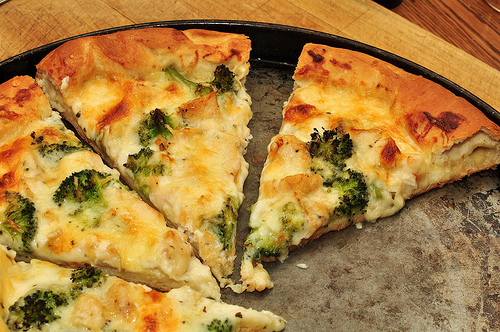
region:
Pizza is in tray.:
[46, 18, 470, 326]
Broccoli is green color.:
[47, 163, 109, 213]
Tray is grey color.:
[328, 198, 492, 328]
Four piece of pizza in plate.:
[38, 95, 300, 326]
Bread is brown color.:
[354, 61, 436, 117]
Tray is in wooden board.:
[262, 8, 456, 85]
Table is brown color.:
[417, 4, 492, 42]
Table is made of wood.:
[418, 5, 460, 50]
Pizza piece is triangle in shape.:
[208, 30, 488, 283]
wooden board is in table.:
[397, 11, 469, 55]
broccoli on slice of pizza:
[302, 122, 372, 217]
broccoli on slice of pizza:
[162, 62, 240, 104]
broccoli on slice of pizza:
[134, 107, 180, 147]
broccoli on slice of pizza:
[214, 194, 237, 250]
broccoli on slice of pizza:
[53, 172, 118, 215]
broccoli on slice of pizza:
[3, 190, 38, 249]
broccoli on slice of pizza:
[6, 287, 64, 327]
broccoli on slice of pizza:
[71, 263, 107, 294]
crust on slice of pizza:
[294, 43, 496, 172]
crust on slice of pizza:
[34, 28, 249, 82]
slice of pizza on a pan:
[251, 37, 477, 240]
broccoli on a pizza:
[320, 120, 365, 210]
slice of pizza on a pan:
[180, 35, 234, 212]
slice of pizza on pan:
[0, 70, 67, 228]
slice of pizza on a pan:
[45, 287, 270, 327]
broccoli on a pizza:
[256, 213, 291, 259]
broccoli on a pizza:
[201, 198, 241, 249]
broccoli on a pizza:
[138, 96, 175, 141]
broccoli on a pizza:
[68, 170, 113, 202]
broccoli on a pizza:
[12, 190, 39, 253]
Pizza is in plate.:
[11, 40, 409, 299]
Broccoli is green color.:
[114, 105, 194, 192]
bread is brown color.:
[293, 57, 455, 127]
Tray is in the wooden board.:
[284, 10, 453, 80]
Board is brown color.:
[308, 10, 476, 95]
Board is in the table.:
[391, 4, 493, 71]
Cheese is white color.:
[155, 162, 218, 209]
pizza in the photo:
[14, 51, 434, 305]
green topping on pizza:
[311, 123, 356, 172]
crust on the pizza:
[308, 43, 498, 158]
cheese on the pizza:
[268, 127, 340, 209]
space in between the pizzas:
[228, 75, 296, 183]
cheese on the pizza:
[176, 126, 224, 190]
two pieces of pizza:
[139, 33, 441, 225]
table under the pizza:
[0, 1, 73, 51]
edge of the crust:
[286, 36, 335, 79]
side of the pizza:
[428, 129, 495, 172]